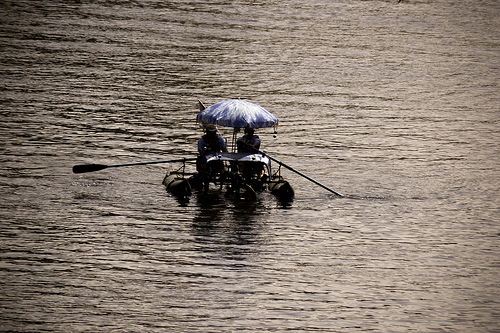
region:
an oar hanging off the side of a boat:
[70, 162, 194, 175]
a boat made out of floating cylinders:
[165, 96, 295, 215]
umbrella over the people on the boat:
[192, 92, 282, 132]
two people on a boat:
[195, 123, 265, 158]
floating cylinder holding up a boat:
[160, 169, 191, 200]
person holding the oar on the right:
[237, 124, 264, 154]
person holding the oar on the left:
[196, 119, 228, 166]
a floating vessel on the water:
[162, 97, 296, 212]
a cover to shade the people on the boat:
[196, 97, 278, 131]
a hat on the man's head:
[202, 121, 218, 136]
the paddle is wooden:
[80, 160, 86, 172]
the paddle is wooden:
[76, 169, 88, 176]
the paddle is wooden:
[96, 164, 103, 167]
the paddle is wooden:
[82, 159, 102, 176]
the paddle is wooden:
[83, 163, 98, 185]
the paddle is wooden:
[74, 167, 94, 185]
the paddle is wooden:
[79, 165, 89, 172]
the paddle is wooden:
[82, 158, 90, 175]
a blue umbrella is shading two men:
[194, 95, 279, 154]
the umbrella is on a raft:
[165, 97, 296, 214]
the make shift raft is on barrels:
[157, 147, 296, 213]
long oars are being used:
[55, 142, 380, 212]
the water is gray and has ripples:
[6, 7, 491, 318]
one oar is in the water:
[252, 147, 383, 231]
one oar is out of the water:
[66, 147, 192, 189]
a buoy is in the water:
[189, 96, 221, 138]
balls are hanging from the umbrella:
[271, 112, 283, 144]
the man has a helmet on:
[202, 122, 221, 141]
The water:
[284, 267, 376, 331]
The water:
[270, 172, 380, 329]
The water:
[251, 198, 326, 303]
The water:
[324, 292, 348, 324]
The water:
[332, 212, 383, 283]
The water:
[334, 228, 379, 320]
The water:
[341, 258, 392, 329]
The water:
[280, 214, 337, 291]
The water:
[310, 200, 412, 328]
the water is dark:
[29, 54, 161, 122]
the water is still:
[318, 74, 448, 141]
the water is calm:
[281, 241, 400, 311]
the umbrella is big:
[200, 89, 285, 137]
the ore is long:
[64, 151, 203, 190]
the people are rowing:
[176, 119, 277, 181]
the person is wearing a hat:
[198, 124, 219, 132]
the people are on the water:
[182, 97, 292, 232]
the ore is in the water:
[296, 156, 345, 209]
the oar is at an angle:
[300, 162, 339, 209]